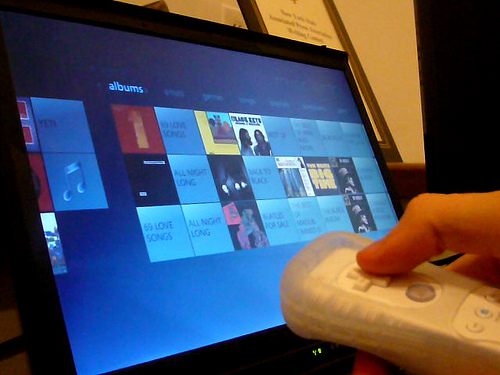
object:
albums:
[108, 103, 164, 153]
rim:
[61, 0, 353, 63]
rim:
[10, 221, 69, 368]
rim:
[368, 133, 400, 208]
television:
[3, 4, 428, 364]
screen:
[5, 19, 417, 375]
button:
[406, 283, 435, 301]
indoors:
[1, 1, 496, 373]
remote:
[282, 230, 500, 375]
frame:
[252, 1, 369, 55]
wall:
[338, 4, 451, 179]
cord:
[0, 333, 27, 358]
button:
[474, 306, 493, 318]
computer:
[3, 0, 409, 373]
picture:
[339, 193, 378, 234]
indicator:
[312, 350, 316, 356]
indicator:
[318, 348, 322, 353]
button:
[467, 322, 484, 332]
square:
[327, 156, 365, 193]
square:
[302, 155, 339, 196]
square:
[240, 152, 287, 201]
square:
[125, 150, 182, 207]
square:
[133, 201, 195, 263]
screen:
[3, 10, 401, 375]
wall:
[334, 2, 426, 166]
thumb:
[366, 163, 493, 308]